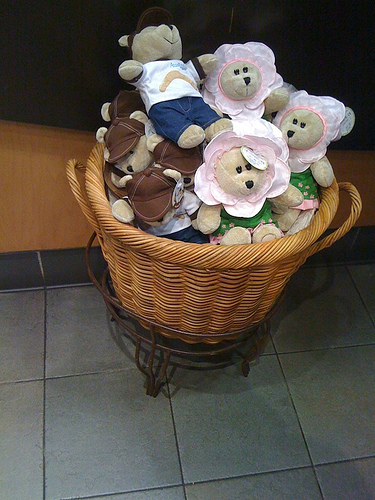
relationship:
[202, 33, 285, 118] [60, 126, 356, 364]
stuffed bear in basket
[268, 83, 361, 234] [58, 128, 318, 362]
bear in basket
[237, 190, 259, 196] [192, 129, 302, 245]
mouth of teddy bear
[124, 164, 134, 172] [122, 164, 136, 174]
nose of teddy bear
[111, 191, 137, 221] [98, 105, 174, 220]
leg of teddy bear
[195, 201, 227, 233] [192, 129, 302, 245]
arm of teddy bear